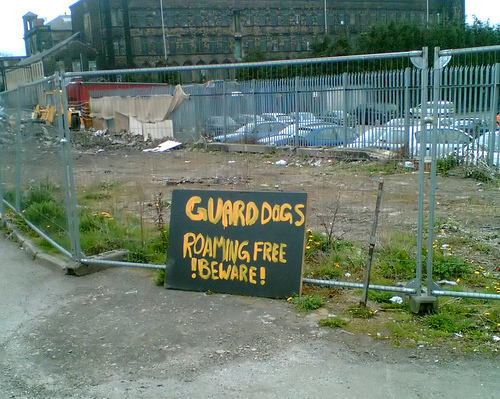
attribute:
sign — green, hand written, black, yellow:
[162, 189, 309, 299]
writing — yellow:
[182, 194, 304, 286]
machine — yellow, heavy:
[31, 88, 86, 132]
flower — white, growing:
[28, 177, 36, 194]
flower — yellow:
[305, 228, 323, 253]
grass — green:
[2, 185, 170, 264]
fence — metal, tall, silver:
[2, 44, 500, 301]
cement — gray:
[0, 229, 499, 397]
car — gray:
[374, 127, 474, 160]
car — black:
[204, 117, 242, 136]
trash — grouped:
[388, 292, 403, 305]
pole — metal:
[358, 177, 384, 308]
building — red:
[65, 74, 167, 113]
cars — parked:
[204, 100, 499, 168]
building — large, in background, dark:
[22, 0, 465, 84]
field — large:
[1, 106, 500, 354]